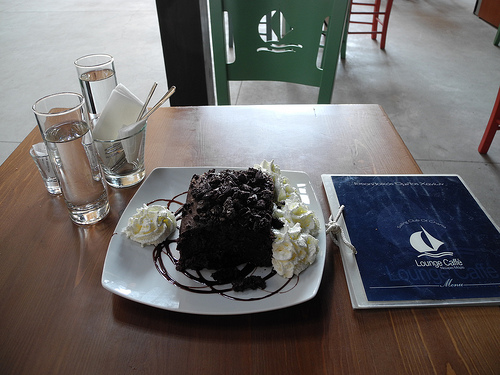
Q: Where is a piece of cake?
A: On a plate.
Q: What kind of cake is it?
A: Chocolate.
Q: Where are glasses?
A: On the table.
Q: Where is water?
A: In the glasses.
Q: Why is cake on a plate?
A: To be eaten.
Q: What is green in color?
A: A chair.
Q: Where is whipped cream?
A: On the plate.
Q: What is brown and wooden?
A: Table.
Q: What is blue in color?
A: Book on table.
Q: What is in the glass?
A: Water.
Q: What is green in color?
A: Chair.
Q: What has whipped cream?
A: Cake.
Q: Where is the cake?
A: Plate.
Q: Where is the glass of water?
A: Table.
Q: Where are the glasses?
A: On the table.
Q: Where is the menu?
A: On the table.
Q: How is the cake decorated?
A: With whipped cream.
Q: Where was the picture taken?
A: In a restaurant.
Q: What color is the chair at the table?
A: Green.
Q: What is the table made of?
A: Wood.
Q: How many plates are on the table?
A: One.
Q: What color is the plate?
A: White.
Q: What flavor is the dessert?
A: Chocolate.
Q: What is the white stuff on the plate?
A: Whipped cream.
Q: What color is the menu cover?
A: Blue.